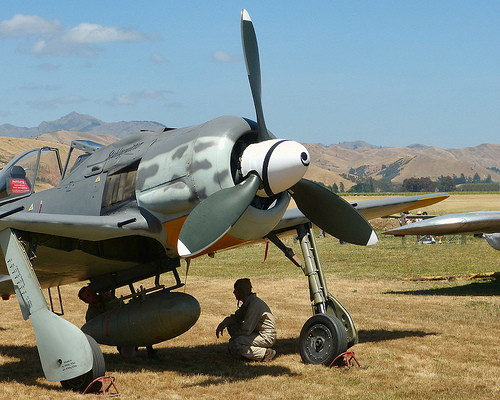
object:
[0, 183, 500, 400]
field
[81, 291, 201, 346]
bomb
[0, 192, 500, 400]
grass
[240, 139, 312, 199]
plane nose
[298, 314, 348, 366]
black wheel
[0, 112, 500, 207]
mountains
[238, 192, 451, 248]
wing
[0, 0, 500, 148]
sky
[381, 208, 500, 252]
plane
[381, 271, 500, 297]
shadow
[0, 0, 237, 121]
cloud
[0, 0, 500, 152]
blue sky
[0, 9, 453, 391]
fighter plane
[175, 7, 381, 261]
propeller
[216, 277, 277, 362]
man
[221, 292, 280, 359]
flight suit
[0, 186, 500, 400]
ground